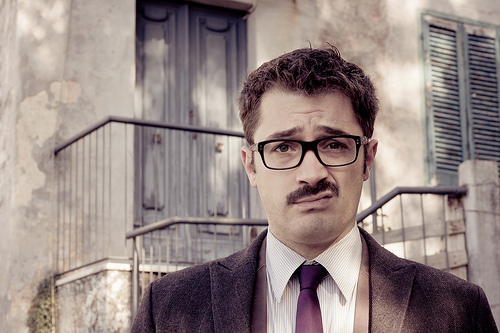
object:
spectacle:
[246, 135, 368, 170]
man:
[126, 38, 497, 332]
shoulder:
[361, 228, 482, 331]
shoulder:
[146, 229, 266, 332]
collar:
[263, 229, 362, 303]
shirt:
[264, 226, 362, 332]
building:
[0, 0, 499, 332]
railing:
[53, 116, 269, 279]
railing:
[354, 184, 467, 282]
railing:
[125, 214, 266, 317]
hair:
[233, 40, 379, 143]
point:
[268, 250, 308, 303]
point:
[311, 256, 364, 302]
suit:
[313, 221, 498, 317]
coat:
[131, 226, 497, 333]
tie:
[294, 263, 324, 333]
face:
[252, 96, 366, 239]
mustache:
[282, 181, 338, 204]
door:
[133, 4, 250, 264]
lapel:
[208, 259, 255, 331]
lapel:
[371, 262, 419, 333]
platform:
[135, 254, 200, 273]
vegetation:
[27, 280, 56, 332]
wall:
[54, 0, 135, 332]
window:
[416, 9, 496, 183]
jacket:
[253, 228, 369, 332]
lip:
[295, 190, 333, 203]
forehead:
[255, 87, 355, 126]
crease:
[287, 107, 323, 116]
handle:
[151, 131, 163, 145]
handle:
[215, 142, 227, 154]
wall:
[257, 0, 496, 250]